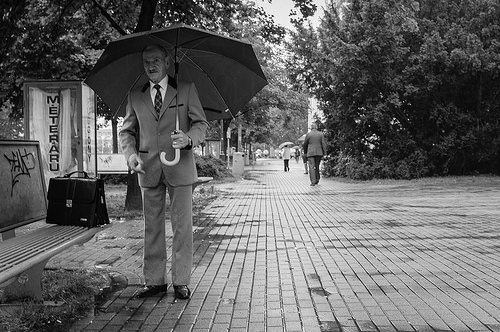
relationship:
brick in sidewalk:
[265, 298, 281, 311] [117, 177, 499, 321]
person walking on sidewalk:
[279, 140, 293, 172] [46, 157, 498, 330]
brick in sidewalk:
[189, 177, 496, 330] [203, 149, 498, 316]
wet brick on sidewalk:
[261, 199, 373, 283] [46, 157, 498, 330]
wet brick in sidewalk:
[238, 275, 275, 313] [203, 182, 497, 326]